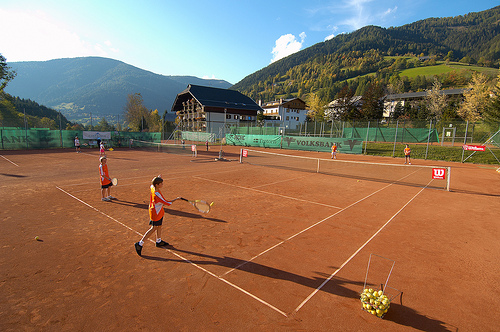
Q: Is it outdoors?
A: Yes, it is outdoors.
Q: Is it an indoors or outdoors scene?
A: It is outdoors.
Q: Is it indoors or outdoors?
A: It is outdoors.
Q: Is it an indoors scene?
A: No, it is outdoors.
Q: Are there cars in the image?
A: No, there are no cars.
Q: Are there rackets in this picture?
A: Yes, there is a racket.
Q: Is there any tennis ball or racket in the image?
A: Yes, there is a racket.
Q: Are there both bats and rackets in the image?
A: No, there is a racket but no bats.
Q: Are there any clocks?
A: No, there are no clocks.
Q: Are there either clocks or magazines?
A: No, there are no clocks or magazines.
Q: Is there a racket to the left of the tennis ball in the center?
A: Yes, there is a racket to the left of the tennis ball.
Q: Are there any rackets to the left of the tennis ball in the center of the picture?
A: Yes, there is a racket to the left of the tennis ball.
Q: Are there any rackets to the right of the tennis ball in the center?
A: No, the racket is to the left of the tennis ball.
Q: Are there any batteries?
A: No, there are no batteries.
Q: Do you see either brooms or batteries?
A: No, there are no batteries or brooms.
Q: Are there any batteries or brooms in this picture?
A: No, there are no batteries or brooms.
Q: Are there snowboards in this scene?
A: No, there are no snowboards.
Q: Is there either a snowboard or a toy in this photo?
A: No, there are no snowboards or toys.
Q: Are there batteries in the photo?
A: No, there are no batteries.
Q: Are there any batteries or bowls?
A: No, there are no batteries or bowls.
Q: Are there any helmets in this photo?
A: No, there are no helmets.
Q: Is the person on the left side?
A: Yes, the person is on the left of the image.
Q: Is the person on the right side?
A: No, the person is on the left of the image.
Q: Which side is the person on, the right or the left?
A: The person is on the left of the image.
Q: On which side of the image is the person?
A: The person is on the left of the image.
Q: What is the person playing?
A: The person is playing tennis.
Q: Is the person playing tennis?
A: Yes, the person is playing tennis.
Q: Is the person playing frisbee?
A: No, the person is playing tennis.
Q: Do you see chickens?
A: No, there are no chickens.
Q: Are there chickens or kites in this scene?
A: No, there are no chickens or kites.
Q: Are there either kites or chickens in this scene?
A: No, there are no chickens or kites.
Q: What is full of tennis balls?
A: The basket is full of tennis balls.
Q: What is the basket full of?
A: The basket is full of tennis balls.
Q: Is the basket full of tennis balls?
A: Yes, the basket is full of tennis balls.